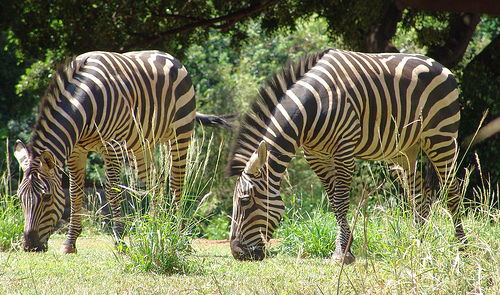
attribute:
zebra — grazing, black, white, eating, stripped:
[13, 48, 197, 255]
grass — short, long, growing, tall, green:
[1, 140, 500, 295]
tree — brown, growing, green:
[112, 3, 499, 211]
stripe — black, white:
[330, 51, 366, 156]